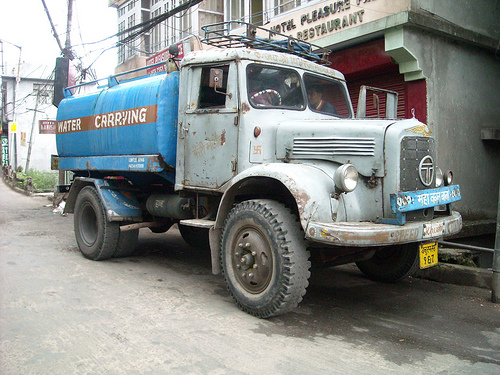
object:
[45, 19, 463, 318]
truck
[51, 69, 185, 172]
tank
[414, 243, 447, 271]
license plate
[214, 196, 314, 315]
front tire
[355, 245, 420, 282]
front tire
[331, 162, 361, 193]
headlight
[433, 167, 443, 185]
headlight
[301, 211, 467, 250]
bumper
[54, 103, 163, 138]
sign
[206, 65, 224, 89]
side mirror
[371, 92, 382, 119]
side mirror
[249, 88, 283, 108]
steering wheel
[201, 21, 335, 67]
rack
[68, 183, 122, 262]
rear tire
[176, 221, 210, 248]
rear tire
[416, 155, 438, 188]
logo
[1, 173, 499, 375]
road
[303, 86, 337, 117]
man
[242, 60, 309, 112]
windshield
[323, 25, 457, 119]
garage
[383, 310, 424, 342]
stain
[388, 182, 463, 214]
sign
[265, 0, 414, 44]
sign